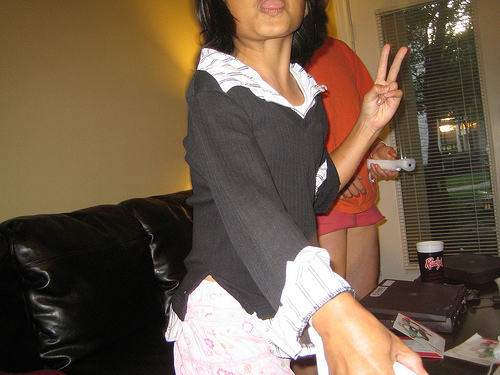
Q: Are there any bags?
A: No, there are no bags.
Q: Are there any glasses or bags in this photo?
A: No, there are no bags or glasses.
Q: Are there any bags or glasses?
A: No, there are no bags or glasses.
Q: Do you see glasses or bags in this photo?
A: No, there are no bags or glasses.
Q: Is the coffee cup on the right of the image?
A: Yes, the coffee cup is on the right of the image.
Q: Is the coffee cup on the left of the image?
A: No, the coffee cup is on the right of the image.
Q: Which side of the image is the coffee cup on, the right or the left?
A: The coffee cup is on the right of the image.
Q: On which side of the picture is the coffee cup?
A: The coffee cup is on the right of the image.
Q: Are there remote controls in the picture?
A: Yes, there is a remote control.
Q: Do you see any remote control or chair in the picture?
A: Yes, there is a remote control.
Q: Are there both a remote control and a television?
A: No, there is a remote control but no televisions.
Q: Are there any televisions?
A: No, there are no televisions.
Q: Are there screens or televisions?
A: No, there are no televisions or screens.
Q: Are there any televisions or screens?
A: No, there are no televisions or screens.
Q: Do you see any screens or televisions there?
A: No, there are no televisions or screens.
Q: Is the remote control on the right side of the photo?
A: Yes, the remote control is on the right of the image.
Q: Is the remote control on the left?
A: No, the remote control is on the right of the image.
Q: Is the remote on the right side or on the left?
A: The remote is on the right of the image.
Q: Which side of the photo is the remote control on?
A: The remote control is on the right of the image.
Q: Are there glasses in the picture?
A: No, there are no glasses.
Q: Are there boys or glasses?
A: No, there are no glasses or boys.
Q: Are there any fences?
A: No, there are no fences.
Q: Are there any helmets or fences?
A: No, there are no fences or helmets.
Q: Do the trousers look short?
A: Yes, the trousers are short.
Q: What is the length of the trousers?
A: The trousers are short.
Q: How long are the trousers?
A: The trousers are short.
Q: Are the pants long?
A: No, the pants are short.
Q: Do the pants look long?
A: No, the pants are short.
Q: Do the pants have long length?
A: No, the pants are short.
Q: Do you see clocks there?
A: No, there are no clocks.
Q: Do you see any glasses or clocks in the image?
A: No, there are no clocks or glasses.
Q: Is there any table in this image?
A: Yes, there is a table.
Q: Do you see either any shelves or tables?
A: Yes, there is a table.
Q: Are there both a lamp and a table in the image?
A: No, there is a table but no lamps.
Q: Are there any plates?
A: No, there are no plates.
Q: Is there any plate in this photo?
A: No, there are no plates.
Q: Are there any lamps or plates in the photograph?
A: No, there are no plates or lamps.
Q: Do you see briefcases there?
A: Yes, there is a briefcase.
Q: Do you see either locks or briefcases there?
A: Yes, there is a briefcase.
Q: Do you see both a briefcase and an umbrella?
A: No, there is a briefcase but no umbrellas.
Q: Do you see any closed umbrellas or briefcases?
A: Yes, there is a closed briefcase.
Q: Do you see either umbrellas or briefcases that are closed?
A: Yes, the briefcase is closed.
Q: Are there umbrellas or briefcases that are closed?
A: Yes, the briefcase is closed.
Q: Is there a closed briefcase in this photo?
A: Yes, there is a closed briefcase.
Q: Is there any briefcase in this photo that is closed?
A: Yes, there is a briefcase that is closed.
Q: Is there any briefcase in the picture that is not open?
A: Yes, there is an closed briefcase.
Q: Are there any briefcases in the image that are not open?
A: Yes, there is an closed briefcase.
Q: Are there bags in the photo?
A: No, there are no bags.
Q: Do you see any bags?
A: No, there are no bags.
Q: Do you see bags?
A: No, there are no bags.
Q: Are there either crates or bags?
A: No, there are no bags or crates.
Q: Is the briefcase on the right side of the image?
A: Yes, the briefcase is on the right of the image.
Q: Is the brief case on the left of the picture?
A: No, the brief case is on the right of the image.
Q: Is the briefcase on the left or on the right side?
A: The briefcase is on the right of the image.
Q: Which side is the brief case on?
A: The brief case is on the right of the image.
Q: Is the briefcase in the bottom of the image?
A: Yes, the briefcase is in the bottom of the image.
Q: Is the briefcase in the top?
A: No, the briefcase is in the bottom of the image.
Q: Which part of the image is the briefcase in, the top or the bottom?
A: The briefcase is in the bottom of the image.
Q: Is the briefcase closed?
A: Yes, the briefcase is closed.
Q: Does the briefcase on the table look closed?
A: Yes, the brief case is closed.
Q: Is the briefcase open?
A: No, the briefcase is closed.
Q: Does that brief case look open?
A: No, the brief case is closed.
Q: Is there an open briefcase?
A: No, there is a briefcase but it is closed.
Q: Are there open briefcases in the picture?
A: No, there is a briefcase but it is closed.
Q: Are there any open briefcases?
A: No, there is a briefcase but it is closed.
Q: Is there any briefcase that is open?
A: No, there is a briefcase but it is closed.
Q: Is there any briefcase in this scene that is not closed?
A: No, there is a briefcase but it is closed.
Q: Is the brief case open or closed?
A: The brief case is closed.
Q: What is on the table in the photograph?
A: The brief case is on the table.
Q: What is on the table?
A: The brief case is on the table.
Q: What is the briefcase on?
A: The briefcase is on the table.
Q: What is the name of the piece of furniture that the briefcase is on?
A: The piece of furniture is a table.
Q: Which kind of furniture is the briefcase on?
A: The briefcase is on the table.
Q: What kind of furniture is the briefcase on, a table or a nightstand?
A: The briefcase is on a table.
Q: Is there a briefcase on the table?
A: Yes, there is a briefcase on the table.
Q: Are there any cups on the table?
A: No, there is a briefcase on the table.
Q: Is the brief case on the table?
A: Yes, the brief case is on the table.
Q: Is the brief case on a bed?
A: No, the brief case is on the table.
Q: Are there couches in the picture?
A: Yes, there is a couch.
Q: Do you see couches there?
A: Yes, there is a couch.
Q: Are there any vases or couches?
A: Yes, there is a couch.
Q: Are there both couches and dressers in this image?
A: No, there is a couch but no dressers.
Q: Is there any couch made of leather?
A: Yes, there is a couch that is made of leather.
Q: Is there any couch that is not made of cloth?
A: Yes, there is a couch that is made of leather.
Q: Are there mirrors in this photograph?
A: No, there are no mirrors.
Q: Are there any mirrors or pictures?
A: No, there are no mirrors or pictures.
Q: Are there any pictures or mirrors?
A: No, there are no mirrors or pictures.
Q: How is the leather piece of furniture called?
A: The piece of furniture is a couch.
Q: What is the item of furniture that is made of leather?
A: The piece of furniture is a couch.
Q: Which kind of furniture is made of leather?
A: The furniture is a couch.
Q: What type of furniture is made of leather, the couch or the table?
A: The couch is made of leather.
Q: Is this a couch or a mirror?
A: This is a couch.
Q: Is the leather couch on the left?
A: Yes, the couch is on the left of the image.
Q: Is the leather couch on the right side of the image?
A: No, the couch is on the left of the image.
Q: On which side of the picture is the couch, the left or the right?
A: The couch is on the left of the image.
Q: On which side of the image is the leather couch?
A: The couch is on the left of the image.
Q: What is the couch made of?
A: The couch is made of leather.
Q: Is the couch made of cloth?
A: No, the couch is made of leather.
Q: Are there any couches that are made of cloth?
A: No, there is a couch but it is made of leather.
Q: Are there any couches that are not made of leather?
A: No, there is a couch but it is made of leather.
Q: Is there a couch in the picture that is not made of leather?
A: No, there is a couch but it is made of leather.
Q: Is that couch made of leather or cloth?
A: The couch is made of leather.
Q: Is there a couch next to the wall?
A: Yes, there is a couch next to the wall.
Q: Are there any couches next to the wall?
A: Yes, there is a couch next to the wall.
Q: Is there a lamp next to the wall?
A: No, there is a couch next to the wall.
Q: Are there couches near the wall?
A: Yes, there is a couch near the wall.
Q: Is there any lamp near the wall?
A: No, there is a couch near the wall.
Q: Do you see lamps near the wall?
A: No, there is a couch near the wall.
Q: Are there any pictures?
A: No, there are no pictures.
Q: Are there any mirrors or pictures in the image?
A: No, there are no pictures or mirrors.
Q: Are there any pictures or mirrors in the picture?
A: No, there are no pictures or mirrors.